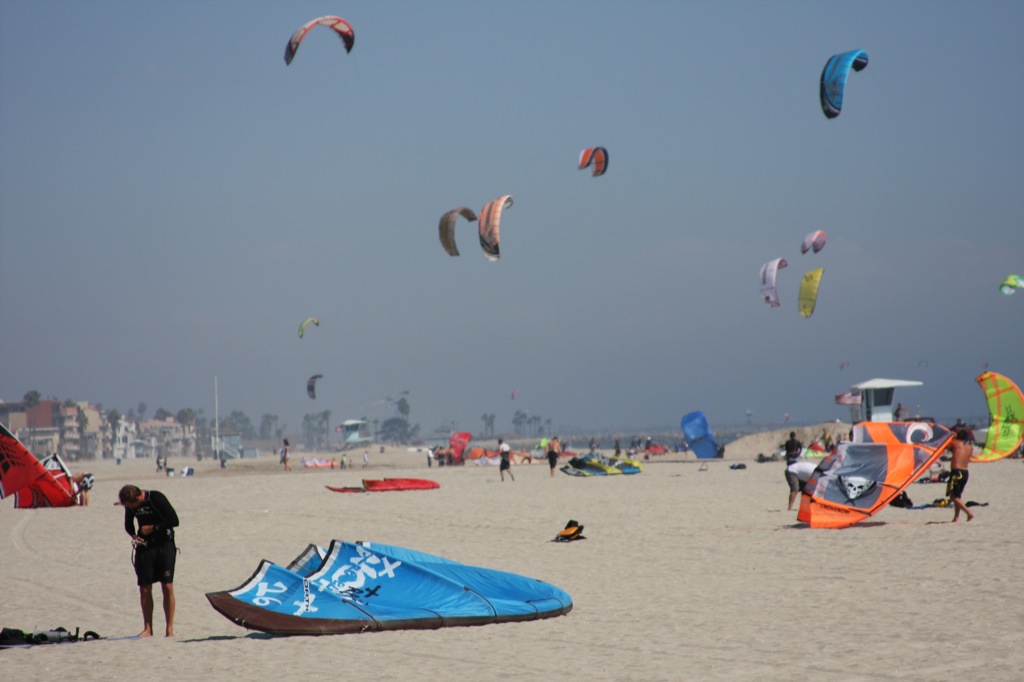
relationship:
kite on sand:
[678, 404, 724, 465] [552, 453, 812, 546]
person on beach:
[481, 420, 542, 485] [289, 471, 776, 660]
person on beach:
[527, 424, 577, 485] [455, 446, 784, 585]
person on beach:
[536, 419, 575, 487] [464, 471, 871, 664]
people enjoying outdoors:
[28, 414, 1022, 657] [25, 29, 1022, 676]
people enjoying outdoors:
[77, 419, 350, 649] [25, 29, 1022, 676]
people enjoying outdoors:
[103, 373, 637, 642] [25, 29, 1022, 676]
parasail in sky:
[436, 198, 512, 278] [13, 10, 1022, 430]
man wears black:
[102, 471, 195, 634] [121, 494, 188, 598]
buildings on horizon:
[6, 382, 430, 460] [17, 404, 985, 459]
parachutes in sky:
[262, 2, 880, 325] [13, 10, 1022, 430]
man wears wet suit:
[102, 471, 195, 634] [121, 490, 188, 583]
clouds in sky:
[162, 241, 288, 371] [13, 10, 1022, 430]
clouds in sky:
[0, 124, 289, 372] [45, 61, 421, 370]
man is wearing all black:
[118, 483, 183, 643] [117, 493, 182, 582]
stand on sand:
[853, 369, 921, 430] [699, 535, 801, 620]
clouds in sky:
[0, 124, 289, 372] [500, 21, 667, 110]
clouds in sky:
[0, 124, 289, 372] [13, 10, 1022, 430]